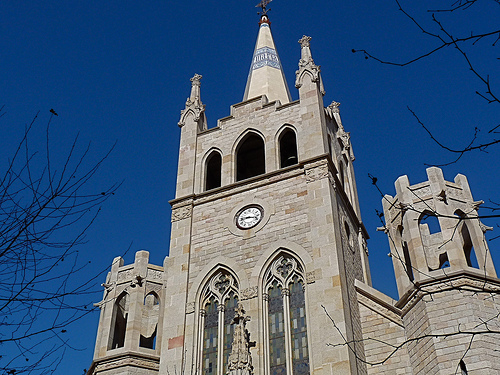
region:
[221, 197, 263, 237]
white clock in tower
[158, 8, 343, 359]
tan colored tower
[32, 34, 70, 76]
blue sky with no clouds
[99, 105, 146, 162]
blue sky with no clouds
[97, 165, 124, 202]
blue sky with no clouds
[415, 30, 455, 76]
blue sky with no clouds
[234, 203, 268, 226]
Clock is on a building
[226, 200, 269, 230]
Clock on a front of a building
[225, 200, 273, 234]
Clock is on the front of a building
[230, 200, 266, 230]
Clock on a tower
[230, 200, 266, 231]
Clock is on a tower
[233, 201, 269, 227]
Clock is on front of a tower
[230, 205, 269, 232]
Clock on outside of building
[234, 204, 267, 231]
Clock is on outside of building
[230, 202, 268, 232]
Clock is on outside of tower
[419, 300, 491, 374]
A brown tower wall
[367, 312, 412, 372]
A brown tower wall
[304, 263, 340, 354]
A brown tower wall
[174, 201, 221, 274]
A brown tower wall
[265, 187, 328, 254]
A brown tower wall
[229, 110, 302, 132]
A brown tower wall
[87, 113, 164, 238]
A blue sky clouds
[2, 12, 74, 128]
A blue sky clouds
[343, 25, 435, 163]
A blue sky clouds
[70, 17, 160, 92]
sky above the building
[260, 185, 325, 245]
bricks on the wall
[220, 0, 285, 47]
top part of the building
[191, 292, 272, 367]
design on the wall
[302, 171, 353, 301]
side of the building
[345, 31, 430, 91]
branch of a tree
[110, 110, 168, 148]
sky with no clouds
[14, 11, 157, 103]
blue sky above the land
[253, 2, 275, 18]
weather vane on church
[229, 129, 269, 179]
opening in church steeple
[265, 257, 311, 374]
stained glass window in tower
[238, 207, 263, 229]
white clock on tower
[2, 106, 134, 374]
tree with no leaves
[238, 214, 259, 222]
black arms on clock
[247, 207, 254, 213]
roman numeral number twelve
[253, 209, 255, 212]
roman numeral number one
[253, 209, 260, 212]
roman numeral number two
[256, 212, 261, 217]
roman numeral number three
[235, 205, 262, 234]
clock on the church tower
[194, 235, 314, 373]
stained glass windows on the church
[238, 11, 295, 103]
spire on the chuch tower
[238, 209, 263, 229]
number marks on the clock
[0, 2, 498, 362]
clear blue sky behind the church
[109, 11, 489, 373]
white stone church with clock tower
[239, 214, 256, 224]
black hands on the clock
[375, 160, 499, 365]
tower on the right side